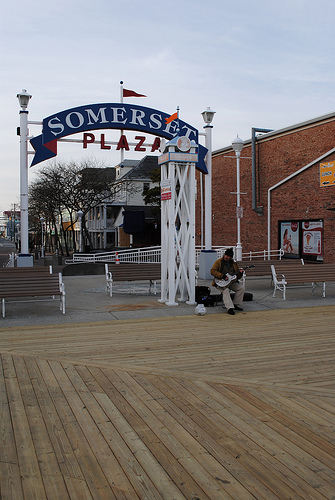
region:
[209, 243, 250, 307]
a man playing a guitar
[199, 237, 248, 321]
a man sitting on a bench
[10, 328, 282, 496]
the wood on the ground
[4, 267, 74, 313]
an empty bench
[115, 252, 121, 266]
an orange cone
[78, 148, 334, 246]
buildings in the background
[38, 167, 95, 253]
a tree next to the buildings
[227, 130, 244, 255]
a white street light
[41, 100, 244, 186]
a sign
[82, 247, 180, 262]
a white fence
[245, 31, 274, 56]
white clouds in blue sky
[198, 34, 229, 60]
white clouds in blue sky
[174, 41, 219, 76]
white clouds in blue sky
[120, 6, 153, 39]
white clouds in blue sky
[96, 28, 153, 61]
white clouds in blue sky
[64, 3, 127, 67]
white clouds in blue sky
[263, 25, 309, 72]
white clouds in blue sky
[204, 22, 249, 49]
white clouds in blue sky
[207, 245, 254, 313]
man playing guitar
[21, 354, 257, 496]
wooden boards making up boardwalk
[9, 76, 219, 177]
entrance sign for somerset plaza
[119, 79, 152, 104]
red flag on pole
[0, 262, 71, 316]
benches facing boardwalk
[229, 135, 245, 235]
light on pole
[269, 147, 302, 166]
bricks on side of building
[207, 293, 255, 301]
guitar case under man's legs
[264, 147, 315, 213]
white water drain on building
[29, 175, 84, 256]
trees with no leaves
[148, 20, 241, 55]
white clouds in blue sky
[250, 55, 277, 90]
white clouds in blue sky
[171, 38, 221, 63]
white clouds in blue sky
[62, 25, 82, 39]
white clouds in blue sky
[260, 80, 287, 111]
white clouds in blue sky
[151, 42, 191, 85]
white clouds in blue sky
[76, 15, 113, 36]
white clouds in blue sky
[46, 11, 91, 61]
white clouds in blue sky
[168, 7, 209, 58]
white clouds in blue sky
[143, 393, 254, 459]
a wooden deck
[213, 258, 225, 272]
man is wearing a brown jacket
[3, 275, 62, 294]
a bench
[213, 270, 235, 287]
the man is playing the guitar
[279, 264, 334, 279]
a bench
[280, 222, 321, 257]
poster on the wall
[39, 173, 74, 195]
tree branches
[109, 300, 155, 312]
the sidewalk is brown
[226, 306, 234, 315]
the man is wearing black shoes